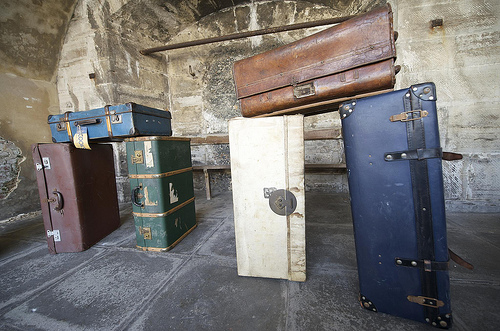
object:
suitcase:
[45, 103, 173, 144]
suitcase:
[337, 81, 453, 329]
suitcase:
[230, 6, 396, 119]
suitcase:
[226, 114, 308, 282]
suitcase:
[30, 141, 122, 255]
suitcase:
[122, 135, 200, 252]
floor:
[0, 186, 500, 331]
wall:
[2, 0, 498, 225]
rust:
[430, 18, 443, 27]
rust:
[87, 72, 99, 80]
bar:
[139, 11, 365, 56]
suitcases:
[341, 82, 453, 331]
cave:
[0, 0, 500, 331]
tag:
[73, 129, 91, 150]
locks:
[45, 230, 62, 244]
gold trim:
[126, 166, 194, 178]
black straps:
[410, 158, 436, 259]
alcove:
[105, 0, 390, 141]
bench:
[189, 128, 349, 200]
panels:
[123, 257, 291, 331]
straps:
[103, 104, 113, 137]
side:
[41, 223, 121, 258]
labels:
[168, 182, 181, 204]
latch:
[269, 190, 298, 217]